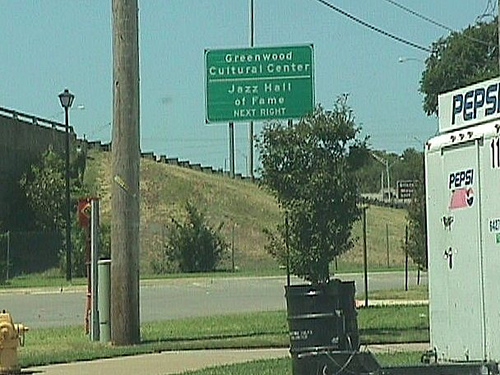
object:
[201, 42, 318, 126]
road sign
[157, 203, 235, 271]
bush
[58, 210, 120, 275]
bush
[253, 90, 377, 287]
tree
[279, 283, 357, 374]
metal drum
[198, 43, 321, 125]
sign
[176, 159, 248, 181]
fence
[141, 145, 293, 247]
highway ramp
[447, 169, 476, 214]
sign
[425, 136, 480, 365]
door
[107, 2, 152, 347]
post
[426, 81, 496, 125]
signage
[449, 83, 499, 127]
"pepsi"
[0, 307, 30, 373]
fire hydrant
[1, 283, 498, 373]
lawn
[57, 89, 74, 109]
light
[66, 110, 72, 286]
post